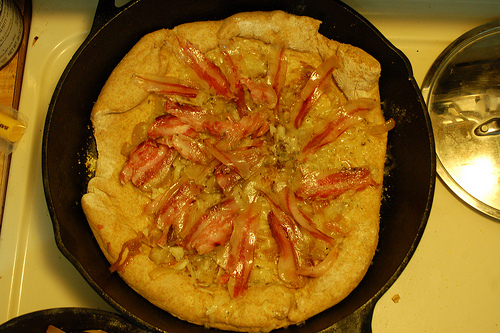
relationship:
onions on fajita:
[121, 41, 396, 292] [84, 13, 394, 330]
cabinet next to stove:
[4, 4, 29, 208] [6, 4, 499, 325]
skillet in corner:
[1, 306, 143, 331] [5, 217, 134, 332]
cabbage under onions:
[129, 51, 352, 287] [121, 41, 396, 292]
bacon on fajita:
[123, 42, 372, 290] [84, 10, 389, 330]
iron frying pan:
[38, 2, 434, 329] [41, 2, 441, 332]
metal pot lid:
[423, 22, 500, 221] [422, 19, 500, 221]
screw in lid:
[477, 121, 490, 134] [422, 19, 500, 221]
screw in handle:
[477, 121, 490, 134] [475, 116, 500, 137]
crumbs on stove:
[391, 293, 404, 301] [6, 4, 499, 325]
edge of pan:
[2, 306, 141, 332] [1, 306, 143, 331]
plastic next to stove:
[1, 100, 30, 158] [6, 4, 499, 325]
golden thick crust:
[82, 11, 388, 327] [85, 14, 390, 329]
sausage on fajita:
[117, 37, 372, 298] [84, 10, 389, 330]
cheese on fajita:
[137, 50, 367, 285] [84, 10, 389, 330]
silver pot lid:
[423, 22, 500, 221] [422, 19, 500, 221]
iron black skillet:
[38, 2, 434, 329] [41, 2, 441, 332]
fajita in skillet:
[84, 10, 389, 330] [41, 2, 441, 332]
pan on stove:
[41, 2, 441, 332] [6, 4, 499, 325]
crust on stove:
[85, 14, 390, 329] [6, 4, 499, 325]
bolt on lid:
[477, 121, 490, 134] [422, 19, 500, 221]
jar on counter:
[3, 5, 26, 64] [4, 4, 29, 208]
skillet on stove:
[41, 2, 441, 332] [6, 4, 499, 325]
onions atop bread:
[121, 41, 396, 292] [85, 14, 390, 329]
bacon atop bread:
[123, 42, 372, 290] [85, 14, 390, 329]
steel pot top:
[423, 22, 500, 221] [422, 19, 500, 221]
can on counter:
[3, 5, 26, 64] [4, 4, 29, 208]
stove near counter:
[6, 4, 499, 325] [4, 4, 29, 208]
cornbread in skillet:
[82, 11, 388, 332] [41, 2, 441, 332]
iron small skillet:
[38, 2, 434, 329] [41, 2, 441, 332]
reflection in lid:
[438, 92, 496, 213] [422, 19, 500, 221]